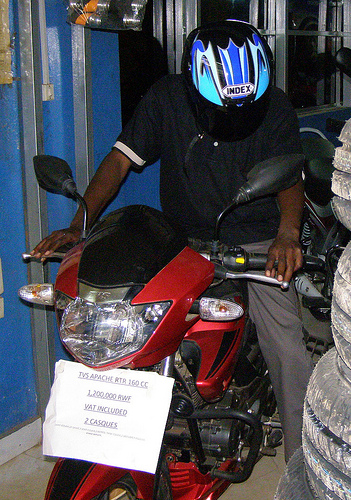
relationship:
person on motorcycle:
[31, 18, 316, 463] [17, 155, 325, 499]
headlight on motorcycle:
[50, 289, 171, 370] [17, 155, 325, 499]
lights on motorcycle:
[18, 283, 244, 360] [17, 155, 325, 499]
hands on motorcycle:
[29, 225, 304, 291] [17, 155, 325, 499]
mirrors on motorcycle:
[33, 154, 305, 203] [17, 155, 325, 499]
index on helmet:
[226, 85, 253, 96] [182, 18, 275, 142]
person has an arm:
[31, 18, 316, 463] [29, 75, 175, 262]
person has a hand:
[31, 18, 316, 463] [31, 226, 84, 264]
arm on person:
[29, 75, 175, 262] [31, 18, 316, 463]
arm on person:
[265, 105, 305, 289] [31, 18, 316, 463]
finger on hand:
[265, 248, 278, 277] [265, 237, 306, 292]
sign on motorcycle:
[42, 359, 175, 475] [17, 155, 325, 499]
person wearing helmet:
[31, 18, 316, 463] [182, 18, 275, 142]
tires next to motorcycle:
[275, 116, 351, 499] [17, 155, 325, 499]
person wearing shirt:
[31, 18, 316, 463] [111, 75, 303, 245]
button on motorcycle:
[235, 257, 246, 267] [17, 155, 325, 499]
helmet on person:
[182, 18, 275, 142] [31, 18, 316, 463]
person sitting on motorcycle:
[31, 18, 316, 463] [17, 155, 325, 499]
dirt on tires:
[273, 117, 349, 499] [275, 116, 351, 499]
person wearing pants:
[31, 18, 316, 463] [232, 237, 315, 466]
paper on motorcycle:
[42, 359, 175, 475] [17, 155, 325, 499]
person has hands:
[31, 18, 316, 463] [29, 225, 304, 291]